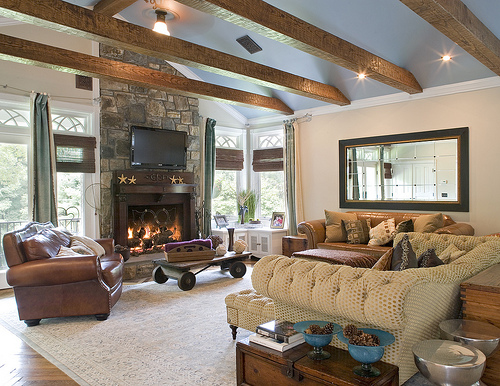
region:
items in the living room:
[75, 328, 165, 366]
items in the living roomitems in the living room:
[128, 177, 196, 234]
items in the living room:
[25, 242, 127, 337]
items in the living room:
[272, 261, 398, 358]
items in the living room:
[107, 113, 205, 203]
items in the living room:
[109, 14, 181, 56]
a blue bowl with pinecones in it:
[340, 320, 392, 374]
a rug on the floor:
[0, 292, 210, 383]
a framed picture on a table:
[267, 206, 289, 231]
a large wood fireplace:
[114, 165, 202, 257]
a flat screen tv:
[128, 125, 188, 172]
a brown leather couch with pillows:
[304, 215, 447, 257]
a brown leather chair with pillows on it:
[2, 221, 123, 330]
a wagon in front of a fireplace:
[150, 249, 253, 294]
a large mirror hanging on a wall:
[333, 120, 472, 210]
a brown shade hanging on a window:
[250, 142, 284, 177]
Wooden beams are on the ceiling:
[0, 0, 497, 120]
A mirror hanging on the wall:
[335, 120, 472, 215]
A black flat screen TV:
[125, 117, 186, 168]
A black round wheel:
[225, 255, 246, 280]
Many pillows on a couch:
[295, 205, 475, 260]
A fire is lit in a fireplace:
[106, 160, 201, 255]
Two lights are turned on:
[350, 47, 460, 88]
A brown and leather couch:
[295, 205, 476, 256]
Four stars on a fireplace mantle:
[112, 165, 188, 186]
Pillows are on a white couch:
[220, 222, 497, 382]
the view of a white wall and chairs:
[200, 102, 276, 105]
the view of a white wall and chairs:
[276, 293, 281, 310]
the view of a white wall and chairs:
[279, 313, 283, 327]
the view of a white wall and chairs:
[278, 310, 294, 336]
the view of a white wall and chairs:
[286, 320, 293, 337]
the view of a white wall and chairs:
[291, 334, 303, 368]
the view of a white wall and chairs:
[274, 258, 280, 325]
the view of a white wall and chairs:
[288, 354, 299, 374]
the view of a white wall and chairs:
[291, 315, 306, 352]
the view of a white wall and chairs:
[286, 297, 312, 375]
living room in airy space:
[8, 12, 488, 377]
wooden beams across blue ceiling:
[6, 9, 494, 111]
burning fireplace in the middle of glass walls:
[4, 92, 290, 277]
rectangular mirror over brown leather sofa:
[297, 123, 473, 256]